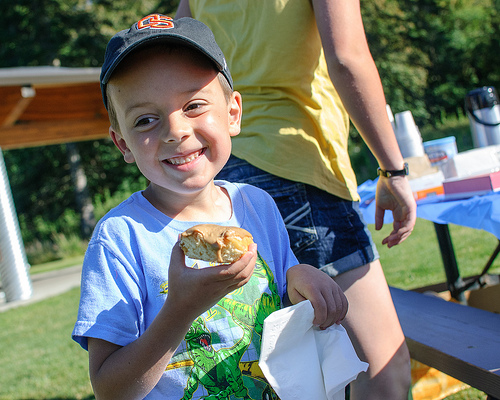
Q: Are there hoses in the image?
A: No, there are no hoses.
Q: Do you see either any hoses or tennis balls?
A: No, there are no hoses or tennis balls.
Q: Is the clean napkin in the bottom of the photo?
A: Yes, the napkin is in the bottom of the image.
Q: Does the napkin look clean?
A: Yes, the napkin is clean.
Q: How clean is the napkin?
A: The napkin is clean.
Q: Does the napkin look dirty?
A: No, the napkin is clean.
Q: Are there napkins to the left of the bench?
A: Yes, there is a napkin to the left of the bench.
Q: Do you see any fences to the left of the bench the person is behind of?
A: No, there is a napkin to the left of the bench.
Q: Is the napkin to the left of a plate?
A: No, the napkin is to the left of the bench.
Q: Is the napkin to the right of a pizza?
A: No, the napkin is to the right of the dinosaur.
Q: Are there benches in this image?
A: Yes, there is a bench.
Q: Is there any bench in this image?
A: Yes, there is a bench.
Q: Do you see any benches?
A: Yes, there is a bench.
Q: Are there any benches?
A: Yes, there is a bench.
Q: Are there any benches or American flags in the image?
A: Yes, there is a bench.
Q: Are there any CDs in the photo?
A: No, there are no cds.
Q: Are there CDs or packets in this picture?
A: No, there are no CDs or packets.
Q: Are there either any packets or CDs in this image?
A: No, there are no CDs or packets.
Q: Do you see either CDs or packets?
A: No, there are no CDs or packets.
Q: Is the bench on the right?
A: Yes, the bench is on the right of the image.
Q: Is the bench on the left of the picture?
A: No, the bench is on the right of the image.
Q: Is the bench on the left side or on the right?
A: The bench is on the right of the image.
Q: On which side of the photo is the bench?
A: The bench is on the right of the image.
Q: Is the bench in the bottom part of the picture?
A: Yes, the bench is in the bottom of the image.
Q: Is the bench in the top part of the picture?
A: No, the bench is in the bottom of the image.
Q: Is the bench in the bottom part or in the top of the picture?
A: The bench is in the bottom of the image.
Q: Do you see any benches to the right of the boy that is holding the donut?
A: Yes, there is a bench to the right of the boy.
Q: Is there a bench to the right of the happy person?
A: Yes, there is a bench to the right of the boy.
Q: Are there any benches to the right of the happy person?
A: Yes, there is a bench to the right of the boy.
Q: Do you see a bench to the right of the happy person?
A: Yes, there is a bench to the right of the boy.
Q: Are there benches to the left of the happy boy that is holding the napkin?
A: No, the bench is to the right of the boy.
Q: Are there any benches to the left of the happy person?
A: No, the bench is to the right of the boy.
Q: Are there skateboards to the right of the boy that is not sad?
A: No, there is a bench to the right of the boy.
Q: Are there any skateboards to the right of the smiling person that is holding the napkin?
A: No, there is a bench to the right of the boy.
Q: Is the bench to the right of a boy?
A: Yes, the bench is to the right of a boy.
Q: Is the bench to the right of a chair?
A: No, the bench is to the right of a boy.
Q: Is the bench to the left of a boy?
A: No, the bench is to the right of a boy.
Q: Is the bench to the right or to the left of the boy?
A: The bench is to the right of the boy.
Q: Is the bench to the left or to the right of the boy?
A: The bench is to the right of the boy.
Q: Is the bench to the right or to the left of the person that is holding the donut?
A: The bench is to the right of the boy.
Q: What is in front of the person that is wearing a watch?
A: The bench is in front of the person.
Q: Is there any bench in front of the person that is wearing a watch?
A: Yes, there is a bench in front of the person.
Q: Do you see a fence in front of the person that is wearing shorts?
A: No, there is a bench in front of the person.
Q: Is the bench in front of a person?
A: Yes, the bench is in front of a person.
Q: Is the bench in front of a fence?
A: No, the bench is in front of a person.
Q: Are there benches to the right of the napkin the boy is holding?
A: Yes, there is a bench to the right of the napkin.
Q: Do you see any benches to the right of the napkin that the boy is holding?
A: Yes, there is a bench to the right of the napkin.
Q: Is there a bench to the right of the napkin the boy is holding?
A: Yes, there is a bench to the right of the napkin.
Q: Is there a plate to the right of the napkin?
A: No, there is a bench to the right of the napkin.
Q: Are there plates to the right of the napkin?
A: No, there is a bench to the right of the napkin.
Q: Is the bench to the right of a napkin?
A: Yes, the bench is to the right of a napkin.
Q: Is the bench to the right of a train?
A: No, the bench is to the right of a napkin.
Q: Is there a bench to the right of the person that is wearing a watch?
A: Yes, there is a bench to the right of the person.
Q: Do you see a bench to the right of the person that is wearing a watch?
A: Yes, there is a bench to the right of the person.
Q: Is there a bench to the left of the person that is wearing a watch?
A: No, the bench is to the right of the person.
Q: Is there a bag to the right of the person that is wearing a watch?
A: No, there is a bench to the right of the person.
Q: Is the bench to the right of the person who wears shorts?
A: Yes, the bench is to the right of the person.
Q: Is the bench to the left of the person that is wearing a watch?
A: No, the bench is to the right of the person.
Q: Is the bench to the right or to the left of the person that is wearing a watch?
A: The bench is to the right of the person.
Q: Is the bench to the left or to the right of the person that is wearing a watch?
A: The bench is to the right of the person.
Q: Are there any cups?
A: Yes, there is a cup.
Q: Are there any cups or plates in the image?
A: Yes, there is a cup.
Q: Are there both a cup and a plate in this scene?
A: No, there is a cup but no plates.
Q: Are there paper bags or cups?
A: Yes, there is a paper cup.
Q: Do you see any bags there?
A: No, there are no bags.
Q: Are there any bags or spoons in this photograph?
A: No, there are no bags or spoons.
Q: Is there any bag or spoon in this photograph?
A: No, there are no bags or spoons.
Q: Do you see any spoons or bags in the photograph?
A: No, there are no bags or spoons.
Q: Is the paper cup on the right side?
A: Yes, the cup is on the right of the image.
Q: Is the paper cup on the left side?
A: No, the cup is on the right of the image.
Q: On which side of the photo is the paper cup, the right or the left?
A: The cup is on the right of the image.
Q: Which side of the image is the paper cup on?
A: The cup is on the right of the image.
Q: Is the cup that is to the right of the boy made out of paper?
A: Yes, the cup is made of paper.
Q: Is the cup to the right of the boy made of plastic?
A: No, the cup is made of paper.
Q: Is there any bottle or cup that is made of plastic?
A: No, there is a cup but it is made of paper.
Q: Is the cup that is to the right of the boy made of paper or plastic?
A: The cup is made of paper.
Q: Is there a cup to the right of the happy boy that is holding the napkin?
A: Yes, there is a cup to the right of the boy.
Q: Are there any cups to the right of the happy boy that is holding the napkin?
A: Yes, there is a cup to the right of the boy.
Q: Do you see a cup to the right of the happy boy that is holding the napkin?
A: Yes, there is a cup to the right of the boy.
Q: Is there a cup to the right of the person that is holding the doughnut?
A: Yes, there is a cup to the right of the boy.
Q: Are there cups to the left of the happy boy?
A: No, the cup is to the right of the boy.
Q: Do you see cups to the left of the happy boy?
A: No, the cup is to the right of the boy.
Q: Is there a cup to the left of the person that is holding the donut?
A: No, the cup is to the right of the boy.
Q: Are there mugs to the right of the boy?
A: No, there is a cup to the right of the boy.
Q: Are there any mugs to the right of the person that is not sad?
A: No, there is a cup to the right of the boy.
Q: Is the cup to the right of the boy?
A: Yes, the cup is to the right of the boy.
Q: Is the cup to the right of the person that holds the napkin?
A: Yes, the cup is to the right of the boy.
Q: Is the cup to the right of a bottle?
A: No, the cup is to the right of the boy.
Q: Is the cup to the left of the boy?
A: No, the cup is to the right of the boy.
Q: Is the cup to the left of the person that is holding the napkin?
A: No, the cup is to the right of the boy.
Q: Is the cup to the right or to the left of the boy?
A: The cup is to the right of the boy.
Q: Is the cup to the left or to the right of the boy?
A: The cup is to the right of the boy.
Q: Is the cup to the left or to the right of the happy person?
A: The cup is to the right of the boy.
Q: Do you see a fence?
A: No, there are no fences.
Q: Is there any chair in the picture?
A: No, there are no chairs.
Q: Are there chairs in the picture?
A: No, there are no chairs.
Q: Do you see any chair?
A: No, there are no chairs.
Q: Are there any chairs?
A: No, there are no chairs.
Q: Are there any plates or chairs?
A: No, there are no chairs or plates.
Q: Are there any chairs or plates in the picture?
A: No, there are no chairs or plates.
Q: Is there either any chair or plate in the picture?
A: No, there are no chairs or plates.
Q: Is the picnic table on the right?
A: Yes, the picnic table is on the right of the image.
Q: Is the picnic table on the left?
A: No, the picnic table is on the right of the image.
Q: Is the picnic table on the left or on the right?
A: The picnic table is on the right of the image.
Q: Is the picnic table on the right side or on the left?
A: The picnic table is on the right of the image.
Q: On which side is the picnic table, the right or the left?
A: The picnic table is on the right of the image.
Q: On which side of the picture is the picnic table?
A: The picnic table is on the right of the image.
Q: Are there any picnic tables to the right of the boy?
A: Yes, there is a picnic table to the right of the boy.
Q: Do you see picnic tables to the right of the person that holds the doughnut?
A: Yes, there is a picnic table to the right of the boy.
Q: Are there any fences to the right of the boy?
A: No, there is a picnic table to the right of the boy.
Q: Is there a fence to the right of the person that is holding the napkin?
A: No, there is a picnic table to the right of the boy.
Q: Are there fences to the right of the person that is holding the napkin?
A: No, there is a picnic table to the right of the boy.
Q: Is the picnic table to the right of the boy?
A: Yes, the picnic table is to the right of the boy.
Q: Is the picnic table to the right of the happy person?
A: Yes, the picnic table is to the right of the boy.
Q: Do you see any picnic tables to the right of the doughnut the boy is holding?
A: Yes, there is a picnic table to the right of the donut.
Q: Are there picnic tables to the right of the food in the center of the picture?
A: Yes, there is a picnic table to the right of the donut.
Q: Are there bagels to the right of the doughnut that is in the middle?
A: No, there is a picnic table to the right of the donut.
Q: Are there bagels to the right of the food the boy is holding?
A: No, there is a picnic table to the right of the donut.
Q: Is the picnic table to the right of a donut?
A: Yes, the picnic table is to the right of a donut.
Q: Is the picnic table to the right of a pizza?
A: No, the picnic table is to the right of a donut.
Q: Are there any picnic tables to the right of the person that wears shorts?
A: Yes, there is a picnic table to the right of the person.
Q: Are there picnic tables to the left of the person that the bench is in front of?
A: No, the picnic table is to the right of the person.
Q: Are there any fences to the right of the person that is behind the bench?
A: No, there is a picnic table to the right of the person.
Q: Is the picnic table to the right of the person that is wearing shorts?
A: Yes, the picnic table is to the right of the person.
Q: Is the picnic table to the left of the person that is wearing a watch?
A: No, the picnic table is to the right of the person.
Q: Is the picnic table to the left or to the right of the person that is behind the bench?
A: The picnic table is to the right of the person.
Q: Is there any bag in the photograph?
A: No, there are no bags.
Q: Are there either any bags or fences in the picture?
A: No, there are no bags or fences.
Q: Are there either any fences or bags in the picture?
A: No, there are no bags or fences.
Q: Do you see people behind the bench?
A: Yes, there is a person behind the bench.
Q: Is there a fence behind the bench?
A: No, there is a person behind the bench.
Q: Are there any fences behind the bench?
A: No, there is a person behind the bench.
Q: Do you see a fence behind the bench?
A: No, there is a person behind the bench.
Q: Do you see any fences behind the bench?
A: No, there is a person behind the bench.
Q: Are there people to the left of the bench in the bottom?
A: Yes, there is a person to the left of the bench.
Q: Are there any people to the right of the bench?
A: No, the person is to the left of the bench.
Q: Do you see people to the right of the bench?
A: No, the person is to the left of the bench.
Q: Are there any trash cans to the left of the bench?
A: No, there is a person to the left of the bench.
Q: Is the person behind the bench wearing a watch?
A: Yes, the person is wearing a watch.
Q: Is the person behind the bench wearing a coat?
A: No, the person is wearing a watch.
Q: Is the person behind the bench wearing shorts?
A: Yes, the person is wearing shorts.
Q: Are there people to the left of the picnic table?
A: Yes, there is a person to the left of the picnic table.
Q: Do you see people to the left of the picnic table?
A: Yes, there is a person to the left of the picnic table.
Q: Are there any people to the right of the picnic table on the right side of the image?
A: No, the person is to the left of the picnic table.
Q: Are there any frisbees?
A: No, there are no frisbees.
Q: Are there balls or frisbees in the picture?
A: No, there are no frisbees or balls.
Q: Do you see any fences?
A: No, there are no fences.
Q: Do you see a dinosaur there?
A: Yes, there is a dinosaur.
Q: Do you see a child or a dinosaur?
A: Yes, there is a dinosaur.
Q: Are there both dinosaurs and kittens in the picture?
A: No, there is a dinosaur but no kittens.